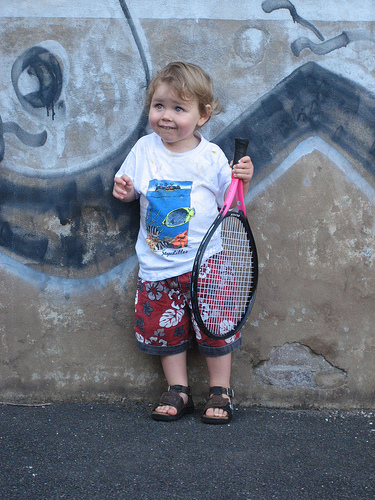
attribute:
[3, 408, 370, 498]
floor — part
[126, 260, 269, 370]
shorts — young , floral pattern 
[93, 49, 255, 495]
boy — Young 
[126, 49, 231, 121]
hair — blonde 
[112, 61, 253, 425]
child — small , standing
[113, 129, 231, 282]
shirt — small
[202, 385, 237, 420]
sandals — brown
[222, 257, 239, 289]
strings — White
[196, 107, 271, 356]
racket — pink , black child's tennis 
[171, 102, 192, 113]
eye — blue 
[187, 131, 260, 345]
tennis racket — tennis 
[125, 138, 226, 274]
shirt — T, white 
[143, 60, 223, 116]
hair — short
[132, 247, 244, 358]
shorts — white flower design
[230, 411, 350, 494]
floor — part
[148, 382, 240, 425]
sandals — pair , brown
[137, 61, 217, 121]
hair — fine, dark blonde 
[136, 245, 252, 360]
shorts — black, white, red, long 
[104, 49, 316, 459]
boy — Young 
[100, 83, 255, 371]
boy — young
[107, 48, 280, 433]
young boy — Young 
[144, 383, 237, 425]
cheppal — brown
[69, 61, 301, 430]
boy — foreground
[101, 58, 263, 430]
child — small 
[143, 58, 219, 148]
head — child's 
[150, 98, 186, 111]
eyes — blue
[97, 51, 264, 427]
boy — Young boy's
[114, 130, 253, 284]
shirt — white 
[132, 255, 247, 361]
shorts — flowered, red 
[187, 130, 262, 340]
racket — pink 